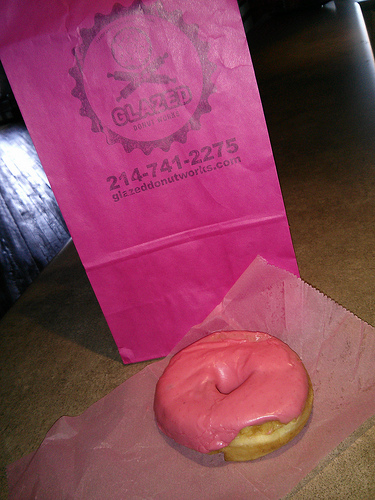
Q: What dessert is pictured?
A: Donut.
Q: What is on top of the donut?
A: Frosting.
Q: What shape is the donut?
A: Circular.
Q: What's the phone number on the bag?
A: 214-741-2275.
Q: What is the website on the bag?
A: Glazeddonutworks.com.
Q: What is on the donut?
A: Glaze.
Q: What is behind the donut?
A: Bag.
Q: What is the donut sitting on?
A: Paper.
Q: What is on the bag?
A: Logo.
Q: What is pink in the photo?
A: Bag and doughnut.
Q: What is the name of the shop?
A: Glazed.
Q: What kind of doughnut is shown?
A: Strawberry.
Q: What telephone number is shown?
A: 2147412275`.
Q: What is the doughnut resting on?
A: Paper.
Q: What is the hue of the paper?
A: Pink.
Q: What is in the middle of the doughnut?
A: A hole.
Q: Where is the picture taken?
A: Kitchen.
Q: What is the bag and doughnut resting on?
A: Countertop.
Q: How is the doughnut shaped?
A: Roundly.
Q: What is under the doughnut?
A: Waxed paper.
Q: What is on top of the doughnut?
A: Pink icing.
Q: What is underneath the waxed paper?
A: A counter.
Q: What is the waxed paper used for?
A: As a doughnut wrapper.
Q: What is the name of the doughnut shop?
A: Glazed Donut Works.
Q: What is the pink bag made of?
A: Paper.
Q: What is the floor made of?
A: Hardwood.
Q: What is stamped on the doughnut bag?
A: A logo.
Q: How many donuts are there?
A: One.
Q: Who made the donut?
A: Glazed Donut Works.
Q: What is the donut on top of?
A: A piece of paper.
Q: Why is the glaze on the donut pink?
A: Food coloring.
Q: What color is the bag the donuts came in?
A: Pink.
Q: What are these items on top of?
A: A counter.